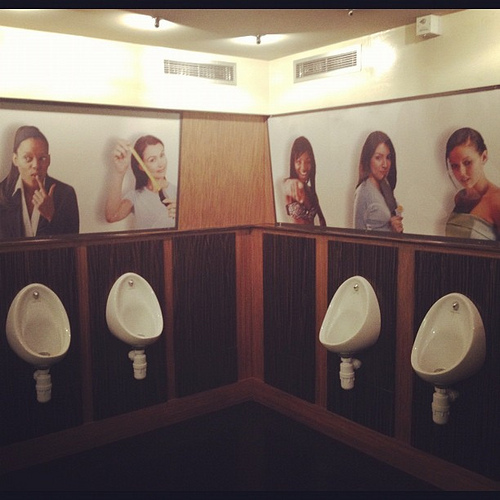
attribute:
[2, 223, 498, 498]
wall — wood, paneled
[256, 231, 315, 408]
panel — wood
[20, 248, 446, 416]
urinals — round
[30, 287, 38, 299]
button — metal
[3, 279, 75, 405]
urinal — white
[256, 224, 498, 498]
walls — wooden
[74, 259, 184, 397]
urinal — white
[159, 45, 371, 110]
plates — metal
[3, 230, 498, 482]
panels — wood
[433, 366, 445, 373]
drain — metal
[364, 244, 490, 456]
urinal — white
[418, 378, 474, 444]
pipe — plastic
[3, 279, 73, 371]
urinal — white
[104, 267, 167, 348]
urinal — white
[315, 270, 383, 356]
urinal — white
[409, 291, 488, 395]
urinal — white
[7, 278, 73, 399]
urinal — white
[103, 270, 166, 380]
urinal — white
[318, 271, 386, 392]
urinal — white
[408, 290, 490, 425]
urinal — four, white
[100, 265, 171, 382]
urinal — white